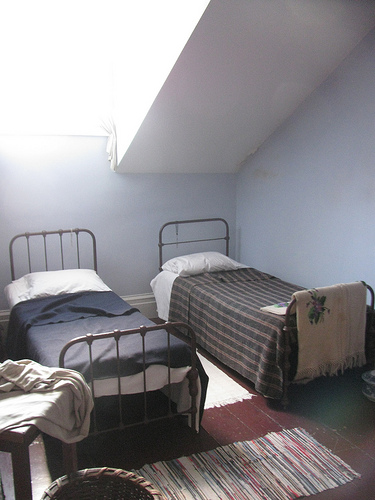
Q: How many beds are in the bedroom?
A: Two.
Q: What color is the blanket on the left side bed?
A: Blue.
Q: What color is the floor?
A: Red.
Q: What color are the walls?
A: White.